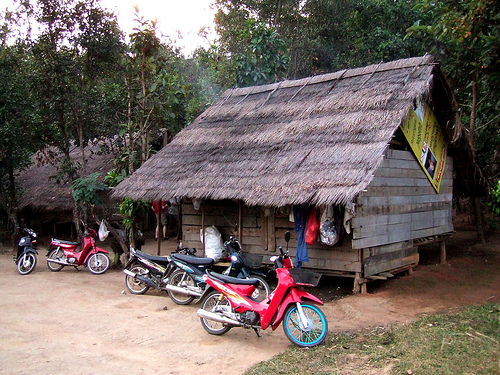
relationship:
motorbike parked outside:
[194, 230, 329, 347] [15, 182, 354, 369]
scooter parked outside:
[167, 242, 243, 298] [15, 182, 354, 369]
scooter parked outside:
[124, 242, 189, 294] [15, 182, 354, 369]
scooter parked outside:
[48, 227, 101, 269] [15, 182, 354, 369]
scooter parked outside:
[13, 228, 37, 274] [15, 182, 354, 369]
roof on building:
[170, 85, 420, 218] [121, 80, 456, 297]